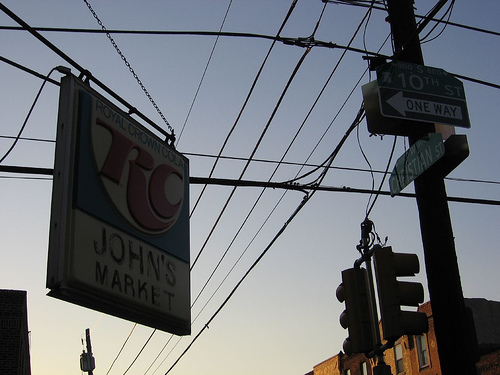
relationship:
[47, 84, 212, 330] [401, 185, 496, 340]
sign on top of pole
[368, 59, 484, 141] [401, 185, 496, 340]
sign on top of pole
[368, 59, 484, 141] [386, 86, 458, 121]
sign has arrow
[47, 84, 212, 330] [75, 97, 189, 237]
sign has rc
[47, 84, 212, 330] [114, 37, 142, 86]
sign has chain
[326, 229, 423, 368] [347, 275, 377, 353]
traffic lights have side